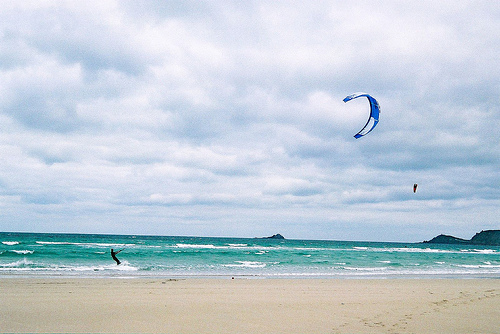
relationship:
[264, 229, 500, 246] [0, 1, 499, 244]
mountains under sky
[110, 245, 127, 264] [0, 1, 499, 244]
person under sky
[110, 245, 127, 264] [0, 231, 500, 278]
person in water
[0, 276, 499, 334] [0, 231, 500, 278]
sand in front of water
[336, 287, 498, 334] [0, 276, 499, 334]
tracks in sand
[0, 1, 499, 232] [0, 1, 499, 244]
clouds in sky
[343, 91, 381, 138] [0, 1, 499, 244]
kite in sky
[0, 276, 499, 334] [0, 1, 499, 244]
sand below sky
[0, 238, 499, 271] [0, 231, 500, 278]
wave in water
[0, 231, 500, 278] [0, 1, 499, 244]
water below sky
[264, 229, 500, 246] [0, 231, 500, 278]
mountains behind water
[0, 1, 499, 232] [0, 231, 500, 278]
clouds above water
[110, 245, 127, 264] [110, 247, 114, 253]
person has head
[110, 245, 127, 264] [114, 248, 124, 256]
person has arms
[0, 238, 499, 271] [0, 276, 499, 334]
wave crashing onto sand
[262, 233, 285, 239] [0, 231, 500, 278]
island in water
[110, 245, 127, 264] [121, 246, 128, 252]
person holding handle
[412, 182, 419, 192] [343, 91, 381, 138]
kite behind kite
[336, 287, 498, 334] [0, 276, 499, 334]
tracks on sand